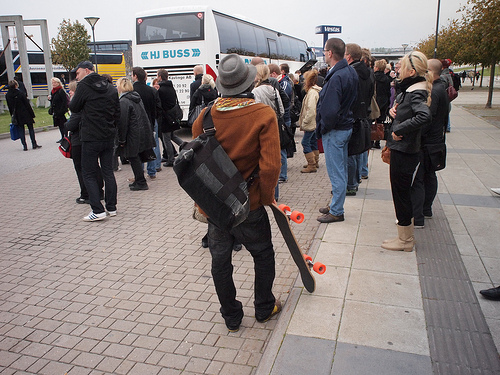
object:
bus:
[131, 7, 318, 126]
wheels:
[302, 254, 327, 275]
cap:
[215, 52, 258, 95]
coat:
[189, 96, 283, 224]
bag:
[172, 99, 260, 233]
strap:
[201, 100, 218, 135]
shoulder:
[201, 102, 217, 137]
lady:
[380, 50, 436, 252]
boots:
[381, 221, 416, 252]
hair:
[398, 50, 434, 108]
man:
[192, 55, 282, 331]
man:
[410, 58, 450, 228]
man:
[344, 43, 371, 195]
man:
[129, 65, 161, 178]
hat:
[70, 60, 94, 73]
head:
[323, 37, 346, 65]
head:
[398, 50, 429, 81]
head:
[427, 58, 444, 76]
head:
[51, 77, 61, 89]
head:
[131, 66, 148, 82]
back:
[131, 4, 220, 122]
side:
[204, 5, 317, 85]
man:
[68, 62, 120, 223]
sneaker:
[82, 210, 108, 222]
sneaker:
[108, 210, 118, 217]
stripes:
[88, 213, 98, 220]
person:
[315, 37, 360, 223]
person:
[373, 58, 392, 149]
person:
[329, 43, 375, 197]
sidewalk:
[255, 103, 500, 374]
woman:
[115, 75, 158, 191]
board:
[269, 201, 327, 293]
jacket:
[118, 90, 157, 162]